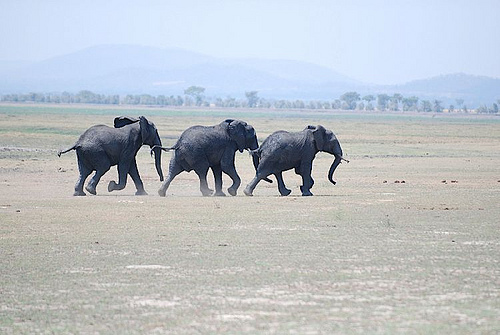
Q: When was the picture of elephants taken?
A: Daytime.